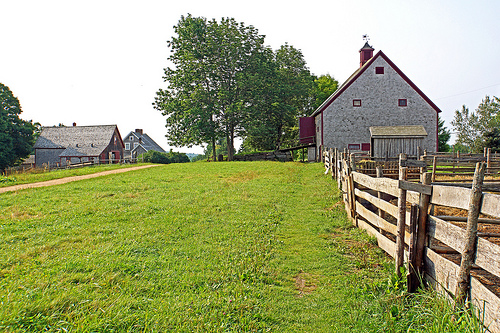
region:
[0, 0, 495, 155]
The sky is gray.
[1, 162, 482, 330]
The grass is green.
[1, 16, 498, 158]
The trees are green.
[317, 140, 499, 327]
The fences are wooden.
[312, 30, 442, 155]
A cupola and a weather vane are on a roof.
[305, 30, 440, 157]
A barn has red trim.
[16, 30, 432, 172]
Three fam related buildings near each other.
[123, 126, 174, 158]
A house has a chimney on the roof.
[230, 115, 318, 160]
A ramp goes up to a building.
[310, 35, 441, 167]
A shed is attached to the side of a building.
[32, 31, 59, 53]
white clouds in blue sky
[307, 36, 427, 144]
white house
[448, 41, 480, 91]
white clouds in blue sky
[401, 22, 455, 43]
white clouds in blue sky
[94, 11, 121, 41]
white clouds in blue sky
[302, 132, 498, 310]
the fence is made of wood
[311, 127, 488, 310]
the fence is made of wood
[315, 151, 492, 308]
the fence is made of wood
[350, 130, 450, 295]
the fence is made of wood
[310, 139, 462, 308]
the fence is made of wood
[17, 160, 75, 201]
the walkway is narrow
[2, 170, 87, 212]
the walkway is narrow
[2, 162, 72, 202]
the walkway is narrow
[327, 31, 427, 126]
white house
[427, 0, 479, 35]
white clouds in blue sky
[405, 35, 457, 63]
white clouds in blue sky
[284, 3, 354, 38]
white clouds in blue sky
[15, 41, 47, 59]
white clouds in blue sky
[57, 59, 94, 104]
white clouds in blue sky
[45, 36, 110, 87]
white clouds in blue sky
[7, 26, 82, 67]
white clouds in blue sky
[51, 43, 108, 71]
white clouds in blue sky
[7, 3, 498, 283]
country farm on a sunny day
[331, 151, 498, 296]
wooden slat fencing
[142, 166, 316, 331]
bright green grass with patches of dirt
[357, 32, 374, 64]
weather vane on top of building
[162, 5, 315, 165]
large stand of trees gently swaying in breeze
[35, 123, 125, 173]
farm building in the distance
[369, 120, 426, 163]
small wooden shed behind building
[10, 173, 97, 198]
dirt pathway running through farm land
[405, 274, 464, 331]
tall grass growing near fence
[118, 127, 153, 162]
small grey house in the distance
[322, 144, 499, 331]
hay inside of old wood fence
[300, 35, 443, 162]
large grey and burgundy barn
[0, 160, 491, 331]
lush green grass with dirt pathway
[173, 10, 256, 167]
A tree in a field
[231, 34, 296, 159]
A tree in a field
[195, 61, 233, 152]
A tree in a field